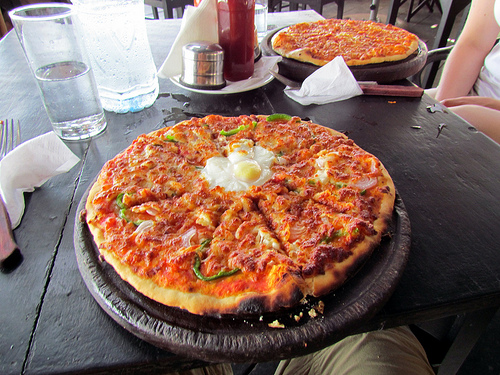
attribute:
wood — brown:
[1, 10, 499, 370]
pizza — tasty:
[84, 111, 396, 317]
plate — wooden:
[72, 164, 412, 359]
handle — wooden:
[347, 84, 424, 97]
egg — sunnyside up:
[199, 140, 277, 192]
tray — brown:
[70, 172, 412, 358]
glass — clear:
[9, 3, 107, 144]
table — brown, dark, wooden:
[0, 7, 492, 373]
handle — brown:
[352, 81, 424, 100]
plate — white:
[164, 57, 281, 97]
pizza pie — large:
[80, 110, 398, 317]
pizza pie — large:
[272, 18, 421, 68]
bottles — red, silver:
[180, 0, 254, 90]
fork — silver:
[1, 120, 21, 158]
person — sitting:
[424, 1, 498, 146]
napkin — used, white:
[285, 54, 362, 108]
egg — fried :
[197, 145, 275, 191]